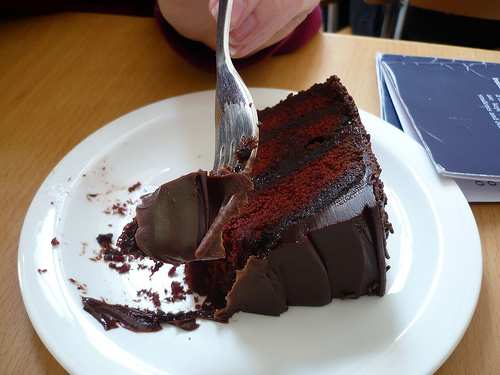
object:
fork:
[209, 0, 257, 175]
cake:
[113, 71, 395, 326]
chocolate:
[204, 170, 384, 323]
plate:
[16, 87, 481, 373]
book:
[371, 51, 499, 204]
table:
[1, 10, 499, 375]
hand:
[156, 0, 322, 59]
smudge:
[81, 295, 200, 332]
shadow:
[226, 289, 402, 374]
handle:
[214, 0, 233, 62]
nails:
[209, 0, 247, 32]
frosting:
[80, 74, 393, 333]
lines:
[245, 71, 379, 257]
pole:
[390, 0, 410, 41]